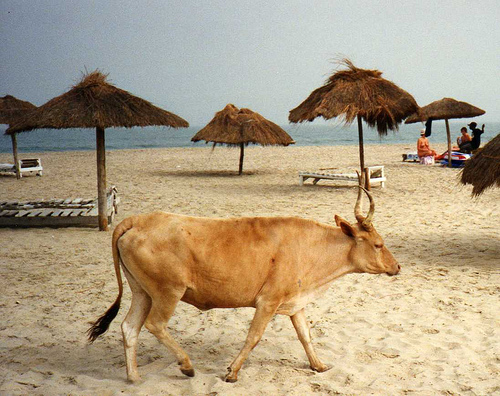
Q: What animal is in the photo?
A: Cow.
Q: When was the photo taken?
A: Daytime.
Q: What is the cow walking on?
A: Sand.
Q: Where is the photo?
A: Beach.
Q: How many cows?
A: One.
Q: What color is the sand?
A: Tan.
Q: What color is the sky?
A: Blue.